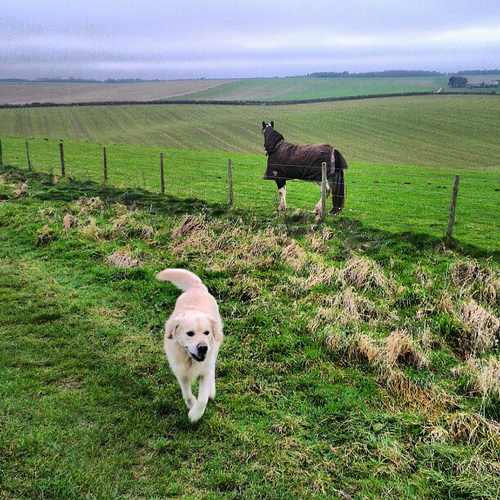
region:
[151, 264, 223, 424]
white dog on a field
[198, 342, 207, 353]
little black nose of dog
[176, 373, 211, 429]
two front legs of dog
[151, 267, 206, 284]
large hairy tail of dog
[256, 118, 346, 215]
brown horse standing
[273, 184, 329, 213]
two left legs of horse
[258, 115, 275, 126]
two little brown ears of horse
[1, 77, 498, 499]
big large field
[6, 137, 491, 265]
large wire fence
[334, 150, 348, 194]
large hairy tail of horse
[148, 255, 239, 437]
tan dog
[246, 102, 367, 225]
brown horse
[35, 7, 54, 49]
white clouds in blue sky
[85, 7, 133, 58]
white clouds in blue sky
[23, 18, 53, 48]
white clouds in blue sky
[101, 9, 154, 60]
white clouds in blue sky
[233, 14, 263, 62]
white clouds in blue sky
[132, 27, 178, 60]
white clouds in blue sky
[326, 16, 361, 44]
white clouds in blue sky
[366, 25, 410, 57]
white clouds in blue sky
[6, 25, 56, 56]
white clouds in blue sky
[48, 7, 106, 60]
white clouds in blue sky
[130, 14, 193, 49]
white clouds in blue sky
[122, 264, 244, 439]
brown dog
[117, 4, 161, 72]
white clouds in blue sky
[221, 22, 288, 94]
white clouds in blue sky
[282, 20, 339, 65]
white clouds in blue sky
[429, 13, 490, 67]
white clouds in blue sky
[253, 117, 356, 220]
Standing horse in pasture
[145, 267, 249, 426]
White dog near horse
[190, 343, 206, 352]
Nose of furry white dog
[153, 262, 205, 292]
Tail of white furry dog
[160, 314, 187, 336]
Ear of furry white dog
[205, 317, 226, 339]
Ear of furry white dog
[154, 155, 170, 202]
Fence post near horse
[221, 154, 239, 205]
Fence post near horse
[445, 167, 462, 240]
Fence post near horse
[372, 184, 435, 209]
Green grassy area near horse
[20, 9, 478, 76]
a gray overcast sky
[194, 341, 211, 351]
a white black dog nose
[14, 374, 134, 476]
lush green grass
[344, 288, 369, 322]
a pile of dead brown grass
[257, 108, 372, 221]
a horse looking into the distance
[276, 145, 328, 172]
a brown blanket on the horse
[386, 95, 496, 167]
a rolling green pasture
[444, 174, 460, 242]
a wooden fence post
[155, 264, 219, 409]
a fluffy white dog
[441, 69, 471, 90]
a large tree in the pasture